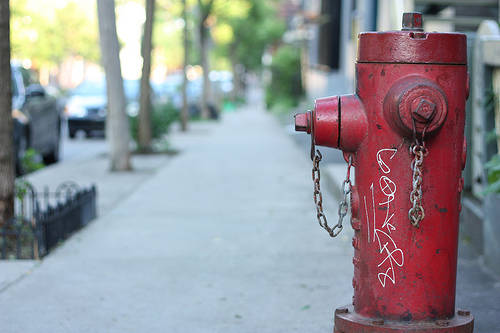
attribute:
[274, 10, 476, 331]
hydrant — red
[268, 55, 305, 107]
bush — green, large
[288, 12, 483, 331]
hydrant — fire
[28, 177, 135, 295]
fence — metal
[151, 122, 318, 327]
sidewalk — long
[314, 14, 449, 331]
hydrant — red, fire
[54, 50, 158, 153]
car — silver, blurry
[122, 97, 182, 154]
bush — green